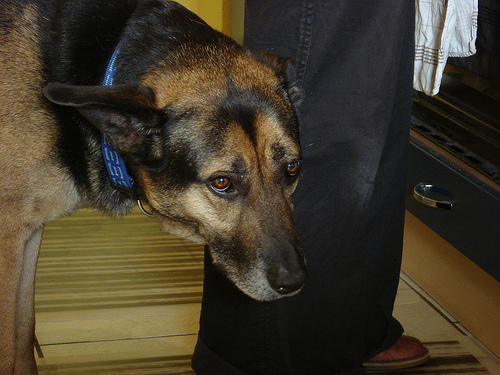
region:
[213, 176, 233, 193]
the eye of a dog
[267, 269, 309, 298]
a black dog's nose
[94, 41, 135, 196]
a blue collar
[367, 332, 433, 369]
a brown shoe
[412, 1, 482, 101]
a white drying towel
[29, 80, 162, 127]
the ear of a dog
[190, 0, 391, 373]
the pants leg of a man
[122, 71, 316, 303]
the head of a dog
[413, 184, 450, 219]
the handle of a drawer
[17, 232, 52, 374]
the leg of a dog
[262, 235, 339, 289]
black nose of the dog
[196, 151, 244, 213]
eye of the dog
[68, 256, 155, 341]
brown floor under dog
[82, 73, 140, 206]
collar on the dog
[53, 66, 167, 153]
ear of the dog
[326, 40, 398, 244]
long black pant leg of the man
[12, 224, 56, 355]
leg of the dog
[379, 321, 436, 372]
shoe of the person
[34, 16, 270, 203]
brown and black dog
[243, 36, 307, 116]
left ear of dog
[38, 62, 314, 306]
this is a dog's head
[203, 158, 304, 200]
these are the dog's eyes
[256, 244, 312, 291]
this is the dog's nose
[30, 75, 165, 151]
this is the dog's ear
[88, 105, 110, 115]
the ear is black in color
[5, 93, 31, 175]
the fur is brown in color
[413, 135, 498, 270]
this is the drawer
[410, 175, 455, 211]
this is the handle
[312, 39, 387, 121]
the trouser is blue in color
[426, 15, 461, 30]
the cloth is white in color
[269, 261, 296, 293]
the nose is black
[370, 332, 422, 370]
the shoes are brown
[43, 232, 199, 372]
the carpet is striped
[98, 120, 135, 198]
the collar is blue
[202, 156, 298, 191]
the eyes are brown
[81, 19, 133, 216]
collar around the neck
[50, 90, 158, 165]
the ear is black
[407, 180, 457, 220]
the handle is silver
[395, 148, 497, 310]
the handle is on drawer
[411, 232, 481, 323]
the floor is brown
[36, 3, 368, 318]
A brown dog with a blue collar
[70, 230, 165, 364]
A striped beige carpet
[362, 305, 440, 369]
A brown shoe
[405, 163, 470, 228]
A silver drawer handle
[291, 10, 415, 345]
A pair of blue jeans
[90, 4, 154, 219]
A blue dog collar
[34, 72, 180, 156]
A dog's ear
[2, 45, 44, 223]
Brown dog fur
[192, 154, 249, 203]
A dog's brown eye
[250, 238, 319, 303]
A dog's black nose